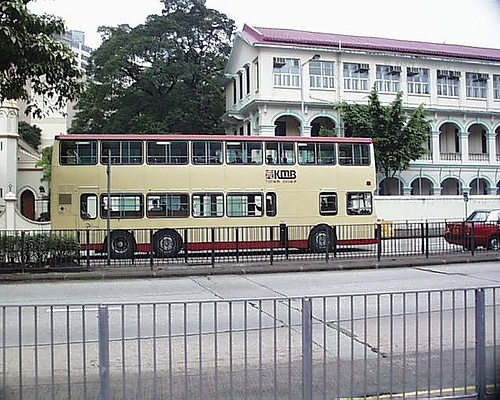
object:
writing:
[262, 167, 298, 185]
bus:
[48, 135, 379, 267]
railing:
[0, 282, 497, 399]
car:
[444, 210, 499, 248]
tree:
[67, 1, 239, 133]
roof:
[235, 20, 498, 68]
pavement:
[0, 257, 498, 400]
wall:
[373, 194, 498, 230]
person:
[265, 154, 276, 163]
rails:
[407, 81, 432, 95]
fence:
[1, 216, 496, 275]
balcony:
[466, 83, 488, 99]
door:
[16, 191, 38, 221]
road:
[379, 223, 458, 255]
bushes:
[0, 232, 82, 270]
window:
[273, 58, 300, 74]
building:
[218, 18, 499, 197]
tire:
[307, 222, 338, 256]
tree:
[328, 82, 437, 198]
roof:
[54, 132, 375, 146]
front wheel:
[105, 227, 134, 260]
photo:
[1, 1, 496, 397]